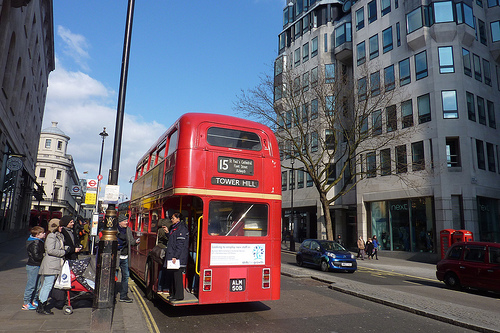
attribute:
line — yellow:
[128, 282, 154, 331]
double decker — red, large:
[128, 112, 280, 305]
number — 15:
[217, 156, 228, 169]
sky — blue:
[41, 0, 282, 209]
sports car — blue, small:
[294, 240, 356, 272]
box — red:
[438, 226, 455, 266]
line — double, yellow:
[122, 272, 160, 330]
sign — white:
[210, 240, 266, 264]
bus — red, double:
[128, 111, 280, 305]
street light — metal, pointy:
[91, 125, 109, 204]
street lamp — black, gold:
[92, 0, 135, 310]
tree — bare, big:
[228, 45, 447, 248]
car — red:
[434, 238, 484, 292]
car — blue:
[292, 235, 359, 273]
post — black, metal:
[88, 1, 138, 331]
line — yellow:
[131, 282, 161, 331]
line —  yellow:
[134, 296, 156, 330]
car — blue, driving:
[298, 238, 359, 272]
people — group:
[14, 204, 79, 310]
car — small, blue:
[296, 235, 364, 285]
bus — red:
[124, 107, 294, 322]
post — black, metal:
[99, 14, 128, 328]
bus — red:
[131, 105, 305, 319]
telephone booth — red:
[433, 231, 477, 292]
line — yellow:
[128, 273, 166, 331]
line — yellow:
[128, 276, 162, 330]